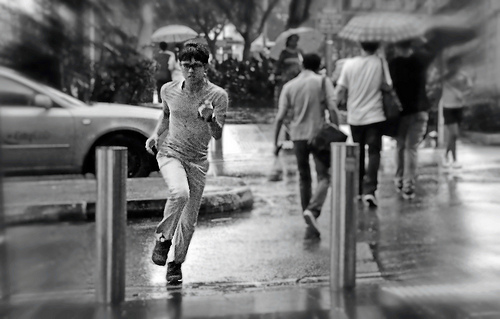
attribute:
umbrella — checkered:
[330, 13, 423, 48]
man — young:
[140, 30, 238, 147]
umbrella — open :
[420, 10, 478, 60]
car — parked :
[2, 62, 188, 184]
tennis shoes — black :
[147, 224, 174, 272]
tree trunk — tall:
[199, 13, 272, 67]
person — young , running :
[155, 24, 228, 285]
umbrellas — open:
[145, 2, 477, 60]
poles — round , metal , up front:
[91, 120, 376, 315]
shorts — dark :
[445, 105, 466, 125]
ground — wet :
[2, 115, 498, 315]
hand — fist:
[198, 91, 220, 131]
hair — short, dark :
[173, 22, 383, 83]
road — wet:
[2, 107, 496, 314]